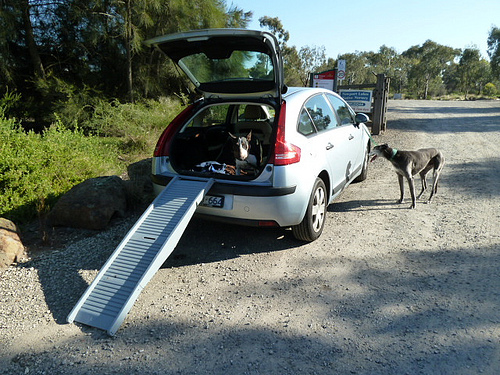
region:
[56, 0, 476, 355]
car on dirt road near trees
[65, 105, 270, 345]
narrow ramp from trunk to ground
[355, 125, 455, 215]
dog standing next to car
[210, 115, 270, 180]
dog sitting in back of trunk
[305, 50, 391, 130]
different signs posted in front of car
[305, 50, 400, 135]
worn wooden posts supporting signs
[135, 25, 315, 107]
hatchback door lifted up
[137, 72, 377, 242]
silver car with long panel of red lights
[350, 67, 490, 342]
shadows along the grey road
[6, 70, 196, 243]
rocks and shrubs next to the car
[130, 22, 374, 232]
Parked silver car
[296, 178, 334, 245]
Black car tire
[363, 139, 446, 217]
Black greyhound dog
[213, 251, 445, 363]
Road is gravel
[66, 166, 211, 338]
Ladder for dog getting out of car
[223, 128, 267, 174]
Dog in back of the car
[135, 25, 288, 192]
Rear door open on car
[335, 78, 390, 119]
Company signs in front of car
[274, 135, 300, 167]
Right side taillight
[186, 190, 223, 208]
License plate tag number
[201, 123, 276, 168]
A dog in the back of a car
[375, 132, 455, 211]
A dog standing beside the car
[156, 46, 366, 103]
The hatch of the car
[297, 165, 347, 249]
A tire on the car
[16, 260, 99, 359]
Gravel on the roadway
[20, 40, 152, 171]
A green forest beside the road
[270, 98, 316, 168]
A taillight on the car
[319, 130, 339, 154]
Black door handle on the car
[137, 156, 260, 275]
A ramp coming out the back of the car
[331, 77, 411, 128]
A sign posted on wood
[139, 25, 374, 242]
White hatchback vehicle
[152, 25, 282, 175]
Open vehicle hatchback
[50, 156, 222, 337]
White wooden ramp into vehicle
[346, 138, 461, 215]
Light gray and white dog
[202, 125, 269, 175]
Black and white dog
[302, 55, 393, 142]
Wooden park entrance sign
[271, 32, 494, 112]
Lush green forested area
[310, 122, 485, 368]
Gray rocky gravel road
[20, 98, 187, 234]
Tall green grass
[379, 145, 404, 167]
Light green dog collar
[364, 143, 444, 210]
dog standing next to white car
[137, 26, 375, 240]
car is a hatchback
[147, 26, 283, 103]
hatch on car is open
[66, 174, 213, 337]
blue ramp leaning against car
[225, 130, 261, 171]
dog in trunk of car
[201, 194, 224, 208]
license plate under ramp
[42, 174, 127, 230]
large rock to the left of car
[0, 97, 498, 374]
car on gravel road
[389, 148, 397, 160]
blue collar on dog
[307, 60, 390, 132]
sign in front of car